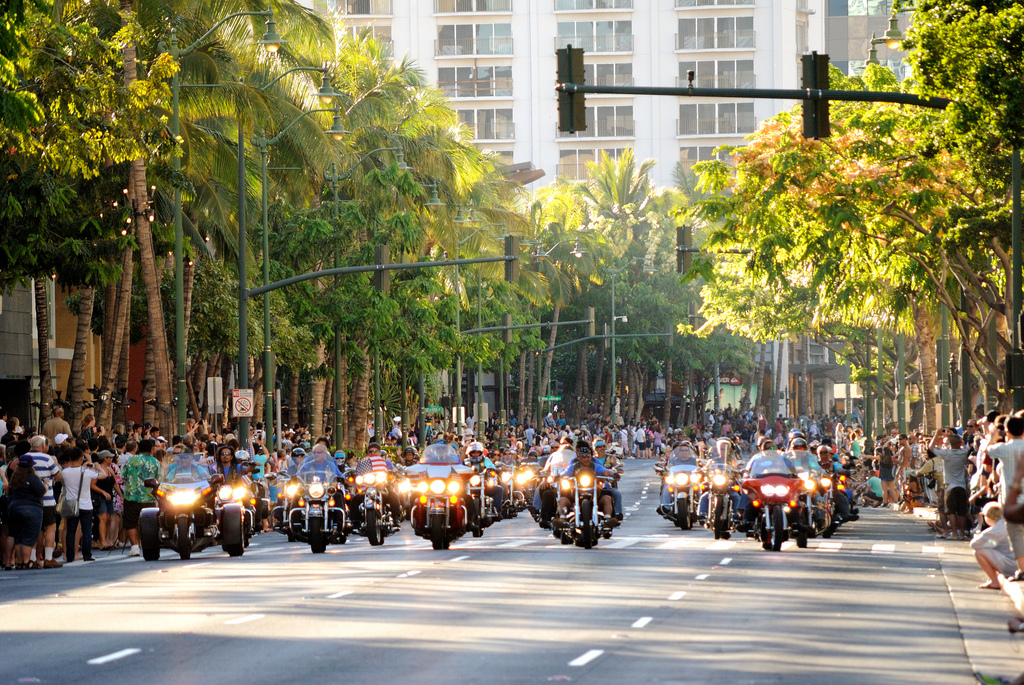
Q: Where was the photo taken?
A: In the city streets.